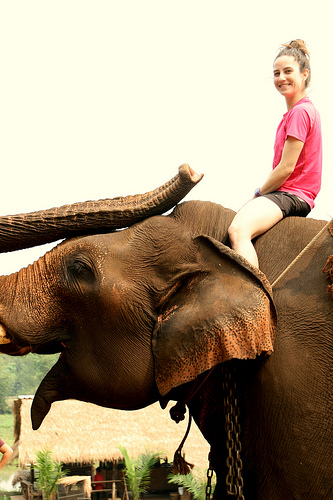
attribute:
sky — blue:
[20, 51, 239, 147]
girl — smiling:
[260, 39, 331, 205]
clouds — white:
[1, 5, 331, 278]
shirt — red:
[273, 95, 321, 209]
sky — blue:
[124, 38, 192, 86]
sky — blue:
[5, 4, 327, 274]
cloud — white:
[115, 102, 197, 143]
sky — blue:
[34, 40, 242, 142]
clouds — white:
[23, 43, 220, 137]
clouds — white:
[91, 40, 231, 131]